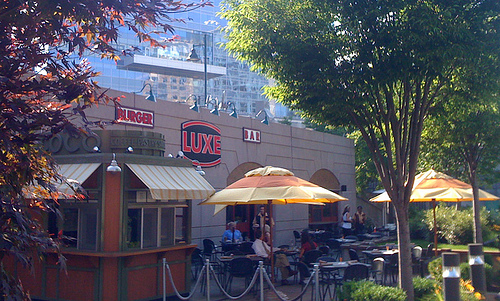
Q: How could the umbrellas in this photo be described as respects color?
A: Orange and white.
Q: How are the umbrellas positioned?
A: Opened.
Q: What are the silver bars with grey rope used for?
A: A barrier.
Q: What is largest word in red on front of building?
A: Luxe.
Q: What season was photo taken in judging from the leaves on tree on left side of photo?
A: Autumn.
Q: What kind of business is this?
A: An outdoor burger bar.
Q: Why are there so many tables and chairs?
A: So people can eat their meals.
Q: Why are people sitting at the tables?
A: They are waiting for their meals.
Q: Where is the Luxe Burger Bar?
A: In the city.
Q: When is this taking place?
A: This is afternoon.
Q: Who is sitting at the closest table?
A: A man and a woman.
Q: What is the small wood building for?
A: It is where you can place your order.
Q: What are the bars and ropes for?
A: To block people from entering the cafe.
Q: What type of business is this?
A: It is a resturant.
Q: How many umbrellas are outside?
A: 2.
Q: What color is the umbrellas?
A: Yellow and orange.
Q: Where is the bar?
A: Left side of the building.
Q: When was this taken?
A: Daytime.